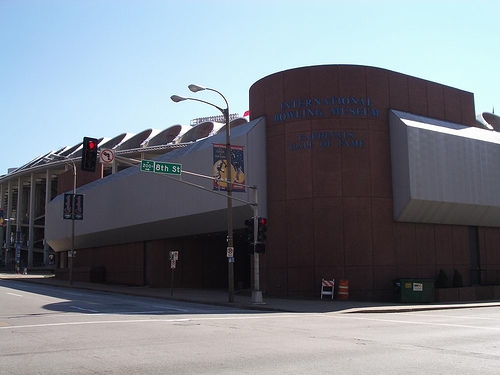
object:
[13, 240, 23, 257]
sign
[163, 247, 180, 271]
sign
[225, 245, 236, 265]
sign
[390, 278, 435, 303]
bin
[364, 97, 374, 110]
words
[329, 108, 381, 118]
words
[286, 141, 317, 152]
words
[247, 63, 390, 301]
corner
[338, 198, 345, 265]
line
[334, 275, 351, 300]
safety cone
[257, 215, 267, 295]
traffic signal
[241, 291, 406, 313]
corner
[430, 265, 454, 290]
bushes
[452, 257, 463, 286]
bushes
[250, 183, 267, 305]
grey pole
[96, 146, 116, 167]
street sign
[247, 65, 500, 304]
building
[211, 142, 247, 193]
sign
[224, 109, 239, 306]
pole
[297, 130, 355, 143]
words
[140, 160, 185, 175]
street sign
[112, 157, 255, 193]
pole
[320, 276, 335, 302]
barricade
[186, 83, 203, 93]
light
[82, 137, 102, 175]
traffic light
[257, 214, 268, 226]
light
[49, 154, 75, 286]
street light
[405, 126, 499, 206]
wall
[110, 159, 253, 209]
pole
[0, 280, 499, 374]
road